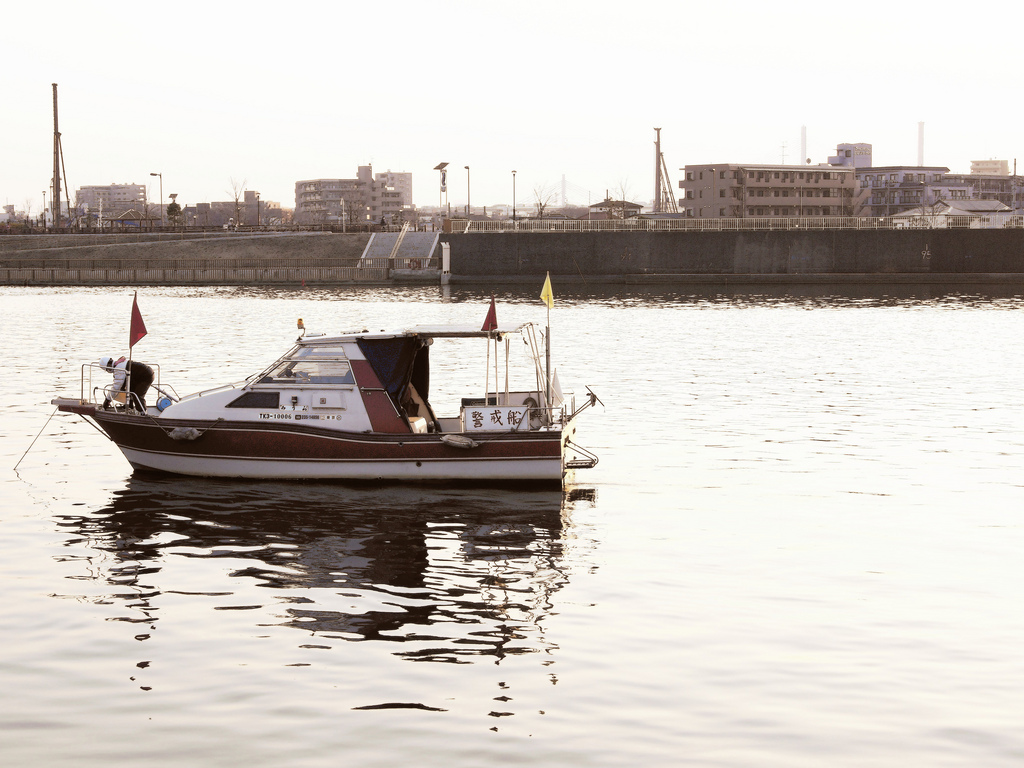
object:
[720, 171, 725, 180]
window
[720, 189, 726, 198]
window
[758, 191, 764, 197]
window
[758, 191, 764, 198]
window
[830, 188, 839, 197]
window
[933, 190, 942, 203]
window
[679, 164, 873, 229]
building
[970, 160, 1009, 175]
building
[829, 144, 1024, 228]
building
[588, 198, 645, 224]
building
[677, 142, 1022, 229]
building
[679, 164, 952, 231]
building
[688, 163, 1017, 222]
city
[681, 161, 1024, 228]
city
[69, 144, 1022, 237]
city